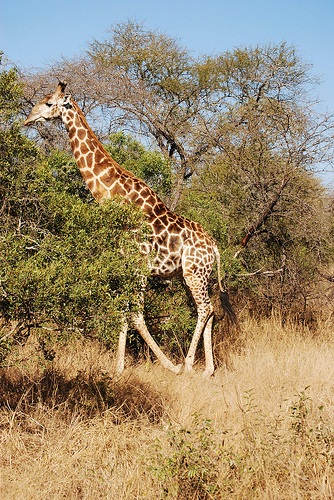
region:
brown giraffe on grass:
[60, 86, 235, 374]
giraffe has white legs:
[113, 302, 225, 380]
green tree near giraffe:
[3, 171, 117, 422]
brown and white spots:
[68, 143, 200, 251]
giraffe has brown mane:
[68, 112, 165, 211]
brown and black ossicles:
[54, 74, 78, 95]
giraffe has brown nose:
[28, 95, 52, 125]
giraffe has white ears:
[48, 99, 76, 107]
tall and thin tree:
[64, 29, 298, 183]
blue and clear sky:
[179, 2, 279, 52]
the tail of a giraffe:
[215, 243, 240, 325]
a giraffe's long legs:
[111, 269, 222, 378]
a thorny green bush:
[0, 150, 150, 379]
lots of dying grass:
[0, 404, 332, 498]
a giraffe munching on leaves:
[16, 82, 233, 371]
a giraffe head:
[23, 80, 73, 124]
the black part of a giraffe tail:
[219, 291, 239, 323]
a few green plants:
[156, 392, 321, 496]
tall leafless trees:
[79, 27, 302, 201]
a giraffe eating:
[24, 79, 76, 126]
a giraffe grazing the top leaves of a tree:
[14, 71, 242, 388]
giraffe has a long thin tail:
[209, 234, 243, 338]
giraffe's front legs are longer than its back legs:
[107, 223, 222, 381]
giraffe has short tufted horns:
[50, 73, 72, 92]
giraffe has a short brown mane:
[67, 91, 143, 180]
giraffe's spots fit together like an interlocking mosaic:
[88, 175, 211, 278]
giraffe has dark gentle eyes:
[39, 97, 58, 109]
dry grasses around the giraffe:
[4, 364, 332, 497]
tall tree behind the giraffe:
[65, 16, 329, 297]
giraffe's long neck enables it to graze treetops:
[20, 75, 141, 212]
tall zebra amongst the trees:
[9, 53, 278, 420]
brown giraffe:
[9, 82, 244, 384]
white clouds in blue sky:
[293, 139, 332, 177]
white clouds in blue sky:
[291, 89, 332, 128]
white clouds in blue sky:
[296, 39, 320, 71]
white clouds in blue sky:
[286, 4, 304, 33]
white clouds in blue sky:
[252, 14, 274, 33]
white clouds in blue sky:
[198, 3, 229, 40]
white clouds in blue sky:
[146, 4, 186, 31]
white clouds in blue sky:
[66, 7, 95, 39]